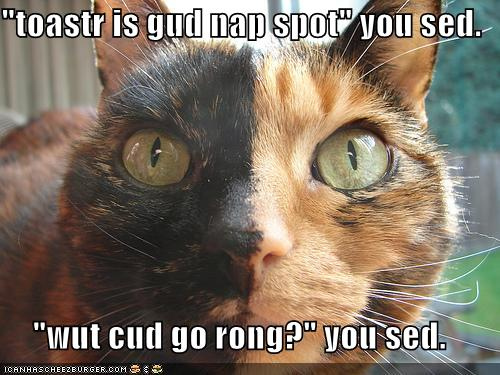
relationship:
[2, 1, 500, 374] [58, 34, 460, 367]
cat has face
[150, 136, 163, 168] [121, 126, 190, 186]
slit in eye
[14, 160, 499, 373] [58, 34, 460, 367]
whiskers coming off face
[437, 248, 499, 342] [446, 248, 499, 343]
field has grass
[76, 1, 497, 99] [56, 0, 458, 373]
hairs on top of head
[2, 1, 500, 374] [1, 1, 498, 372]
cat in picture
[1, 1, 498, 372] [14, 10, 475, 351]
picture has words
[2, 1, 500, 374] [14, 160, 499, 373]
cat has whiskers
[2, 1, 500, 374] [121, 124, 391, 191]
cat has eyes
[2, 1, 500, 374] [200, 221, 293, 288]
cat has nose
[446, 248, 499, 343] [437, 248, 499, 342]
grass in field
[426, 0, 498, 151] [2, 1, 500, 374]
trees behind cat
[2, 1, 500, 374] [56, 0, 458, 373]
cat has head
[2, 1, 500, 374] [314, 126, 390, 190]
cat has eyes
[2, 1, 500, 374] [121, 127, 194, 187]
cat has eye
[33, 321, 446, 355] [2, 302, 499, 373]
words across bottom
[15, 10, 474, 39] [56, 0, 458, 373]
words above head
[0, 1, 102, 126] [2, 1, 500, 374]
wall behind cat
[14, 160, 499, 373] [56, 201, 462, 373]
whiskers on fur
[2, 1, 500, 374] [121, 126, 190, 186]
cat has eye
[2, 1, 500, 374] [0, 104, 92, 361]
cat has back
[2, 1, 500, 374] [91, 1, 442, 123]
cat has ears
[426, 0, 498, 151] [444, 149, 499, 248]
trees behind fence